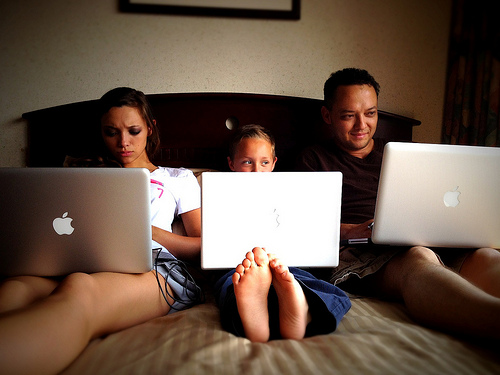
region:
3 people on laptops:
[16, 37, 473, 292]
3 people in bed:
[22, 29, 482, 276]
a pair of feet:
[221, 237, 346, 352]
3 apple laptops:
[13, 140, 480, 270]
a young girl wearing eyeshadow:
[79, 76, 154, 151]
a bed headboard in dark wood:
[34, 56, 411, 153]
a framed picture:
[107, 2, 329, 35]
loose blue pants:
[315, 280, 365, 347]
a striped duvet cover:
[367, 310, 425, 368]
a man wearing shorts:
[331, 95, 482, 313]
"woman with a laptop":
[3, 71, 188, 354]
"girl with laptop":
[196, 110, 341, 345]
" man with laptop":
[325, 60, 496, 340]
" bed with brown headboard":
[20, 85, 430, 370]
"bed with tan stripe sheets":
[15, 80, 485, 370]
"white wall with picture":
[0, 0, 490, 365]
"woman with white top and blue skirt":
[85, 75, 200, 370]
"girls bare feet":
[226, 235, 311, 355]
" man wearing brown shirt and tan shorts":
[320, 60, 496, 335]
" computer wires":
[145, 85, 214, 327]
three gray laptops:
[26, 132, 496, 256]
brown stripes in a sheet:
[135, 317, 191, 368]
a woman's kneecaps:
[10, 269, 100, 310]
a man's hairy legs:
[397, 256, 494, 323]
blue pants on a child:
[293, 260, 339, 327]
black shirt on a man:
[327, 145, 384, 222]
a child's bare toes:
[220, 251, 294, 280]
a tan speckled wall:
[13, 20, 136, 77]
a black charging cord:
[154, 244, 224, 332]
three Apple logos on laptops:
[43, 182, 476, 247]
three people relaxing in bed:
[12, 58, 498, 334]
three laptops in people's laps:
[4, 142, 497, 273]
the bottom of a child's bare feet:
[226, 246, 303, 342]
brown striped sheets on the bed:
[122, 320, 227, 372]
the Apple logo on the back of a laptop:
[49, 201, 80, 239]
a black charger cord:
[149, 249, 203, 311]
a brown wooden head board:
[157, 94, 312, 131]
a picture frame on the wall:
[109, 1, 307, 24]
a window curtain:
[444, 10, 494, 99]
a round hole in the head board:
[220, 105, 243, 133]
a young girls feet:
[201, 227, 333, 367]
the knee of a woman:
[42, 262, 151, 341]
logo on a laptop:
[31, 200, 121, 267]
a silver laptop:
[190, 157, 363, 278]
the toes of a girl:
[230, 240, 263, 284]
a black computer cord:
[149, 226, 212, 311]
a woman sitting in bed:
[0, 80, 195, 353]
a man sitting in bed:
[281, 49, 496, 315]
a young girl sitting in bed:
[165, 94, 356, 354]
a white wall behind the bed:
[148, 37, 270, 93]